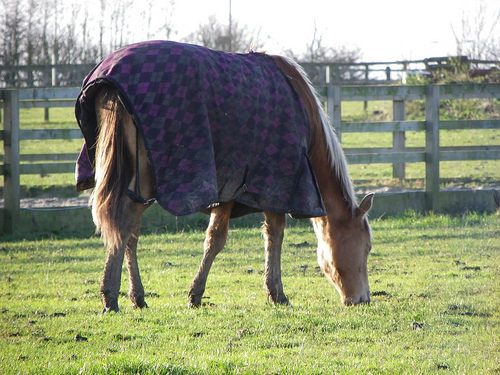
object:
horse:
[73, 40, 376, 315]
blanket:
[72, 39, 327, 219]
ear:
[354, 191, 375, 216]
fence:
[0, 80, 499, 243]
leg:
[186, 207, 234, 310]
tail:
[87, 95, 138, 253]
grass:
[0, 210, 498, 374]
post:
[424, 82, 439, 195]